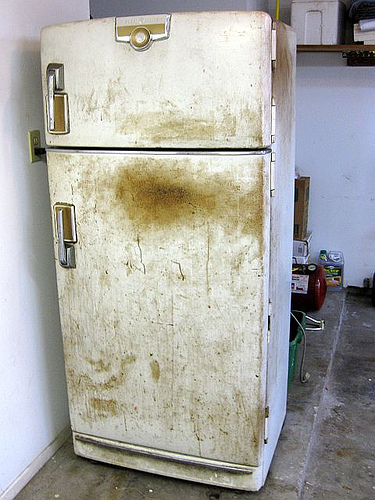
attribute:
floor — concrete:
[286, 303, 371, 498]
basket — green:
[286, 301, 306, 384]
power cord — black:
[36, 144, 47, 156]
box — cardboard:
[289, 233, 317, 263]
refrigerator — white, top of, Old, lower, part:
[38, 11, 295, 492]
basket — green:
[285, 304, 316, 392]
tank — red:
[292, 254, 328, 312]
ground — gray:
[0, 285, 374, 498]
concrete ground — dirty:
[14, 287, 373, 498]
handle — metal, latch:
[44, 62, 56, 131]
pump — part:
[289, 243, 320, 281]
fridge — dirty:
[40, 8, 298, 492]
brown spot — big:
[109, 167, 216, 230]